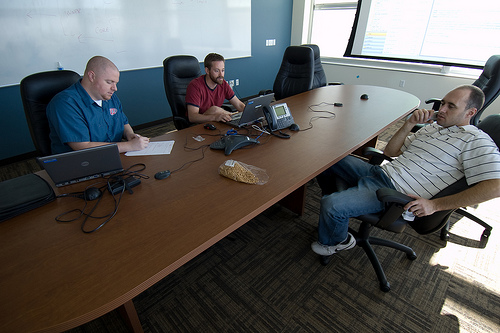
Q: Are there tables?
A: Yes, there is a table.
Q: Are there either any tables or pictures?
A: Yes, there is a table.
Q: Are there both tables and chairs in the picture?
A: Yes, there are both a table and a chair.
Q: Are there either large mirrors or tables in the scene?
A: Yes, there is a large table.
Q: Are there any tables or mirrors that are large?
A: Yes, the table is large.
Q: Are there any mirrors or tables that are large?
A: Yes, the table is large.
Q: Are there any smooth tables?
A: Yes, there is a smooth table.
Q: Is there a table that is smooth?
A: Yes, there is a table that is smooth.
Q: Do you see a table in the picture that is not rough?
A: Yes, there is a smooth table.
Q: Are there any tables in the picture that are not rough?
A: Yes, there is a smooth table.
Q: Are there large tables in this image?
A: Yes, there is a large table.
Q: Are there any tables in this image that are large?
A: Yes, there is a table that is large.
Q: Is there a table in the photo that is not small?
A: Yes, there is a large table.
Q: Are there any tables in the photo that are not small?
A: Yes, there is a large table.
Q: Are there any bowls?
A: No, there are no bowls.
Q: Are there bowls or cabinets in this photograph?
A: No, there are no bowls or cabinets.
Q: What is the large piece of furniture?
A: The piece of furniture is a table.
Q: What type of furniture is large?
A: The furniture is a table.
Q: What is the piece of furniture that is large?
A: The piece of furniture is a table.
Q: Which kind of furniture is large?
A: The furniture is a table.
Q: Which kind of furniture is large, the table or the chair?
A: The table is large.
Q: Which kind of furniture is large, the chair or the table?
A: The table is large.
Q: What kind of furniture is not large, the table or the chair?
A: The chair is not large.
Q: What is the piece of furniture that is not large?
A: The piece of furniture is a chair.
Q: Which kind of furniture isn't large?
A: The furniture is a chair.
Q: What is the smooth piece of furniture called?
A: The piece of furniture is a table.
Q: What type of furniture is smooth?
A: The furniture is a table.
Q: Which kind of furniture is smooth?
A: The furniture is a table.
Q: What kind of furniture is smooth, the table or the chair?
A: The table is smooth.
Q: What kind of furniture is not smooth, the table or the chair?
A: The chair is not smooth.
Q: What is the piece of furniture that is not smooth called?
A: The piece of furniture is a chair.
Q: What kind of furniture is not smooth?
A: The furniture is a chair.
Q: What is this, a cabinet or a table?
A: This is a table.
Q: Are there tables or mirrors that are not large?
A: No, there is a table but it is large.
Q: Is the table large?
A: Yes, the table is large.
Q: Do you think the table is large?
A: Yes, the table is large.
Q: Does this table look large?
A: Yes, the table is large.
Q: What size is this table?
A: The table is large.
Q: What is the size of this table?
A: The table is large.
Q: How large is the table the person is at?
A: The table is large.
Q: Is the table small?
A: No, the table is large.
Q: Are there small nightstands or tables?
A: No, there is a table but it is large.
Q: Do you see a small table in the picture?
A: No, there is a table but it is large.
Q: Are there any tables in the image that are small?
A: No, there is a table but it is large.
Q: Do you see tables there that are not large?
A: No, there is a table but it is large.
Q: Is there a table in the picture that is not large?
A: No, there is a table but it is large.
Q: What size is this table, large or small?
A: The table is large.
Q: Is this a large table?
A: Yes, this is a large table.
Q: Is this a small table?
A: No, this is a large table.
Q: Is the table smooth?
A: Yes, the table is smooth.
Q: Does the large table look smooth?
A: Yes, the table is smooth.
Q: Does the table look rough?
A: No, the table is smooth.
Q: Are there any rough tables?
A: No, there is a table but it is smooth.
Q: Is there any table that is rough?
A: No, there is a table but it is smooth.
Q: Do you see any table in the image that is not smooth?
A: No, there is a table but it is smooth.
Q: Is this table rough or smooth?
A: The table is smooth.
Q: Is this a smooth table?
A: Yes, this is a smooth table.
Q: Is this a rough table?
A: No, this is a smooth table.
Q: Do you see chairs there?
A: Yes, there is a chair.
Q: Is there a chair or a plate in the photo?
A: Yes, there is a chair.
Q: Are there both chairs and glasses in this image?
A: No, there is a chair but no glasses.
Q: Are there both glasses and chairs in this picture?
A: No, there is a chair but no glasses.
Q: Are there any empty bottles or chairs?
A: Yes, there is an empty chair.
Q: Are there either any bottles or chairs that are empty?
A: Yes, the chair is empty.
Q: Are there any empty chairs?
A: Yes, there is an empty chair.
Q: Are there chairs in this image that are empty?
A: Yes, there is a chair that is empty.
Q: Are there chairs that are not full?
A: Yes, there is a empty chair.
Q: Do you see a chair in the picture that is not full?
A: Yes, there is a empty chair.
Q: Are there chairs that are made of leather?
A: Yes, there is a chair that is made of leather.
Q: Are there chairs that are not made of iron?
A: Yes, there is a chair that is made of leather.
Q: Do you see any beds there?
A: No, there are no beds.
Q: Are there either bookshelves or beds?
A: No, there are no beds or bookshelves.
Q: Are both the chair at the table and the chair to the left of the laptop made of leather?
A: Yes, both the chair and the chair are made of leather.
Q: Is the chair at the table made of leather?
A: Yes, the chair is made of leather.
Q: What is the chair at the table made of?
A: The chair is made of leather.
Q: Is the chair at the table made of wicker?
A: No, the chair is made of leather.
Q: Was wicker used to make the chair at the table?
A: No, the chair is made of leather.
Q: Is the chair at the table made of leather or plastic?
A: The chair is made of leather.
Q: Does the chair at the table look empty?
A: Yes, the chair is empty.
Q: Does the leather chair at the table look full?
A: No, the chair is empty.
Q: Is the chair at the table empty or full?
A: The chair is empty.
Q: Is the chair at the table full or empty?
A: The chair is empty.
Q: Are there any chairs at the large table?
A: Yes, there is a chair at the table.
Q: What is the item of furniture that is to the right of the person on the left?
A: The piece of furniture is a chair.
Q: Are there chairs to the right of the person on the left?
A: Yes, there is a chair to the right of the person.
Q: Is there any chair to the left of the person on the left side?
A: No, the chair is to the right of the person.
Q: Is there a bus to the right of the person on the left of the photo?
A: No, there is a chair to the right of the person.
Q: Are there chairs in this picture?
A: Yes, there is a chair.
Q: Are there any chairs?
A: Yes, there is a chair.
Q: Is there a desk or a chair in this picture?
A: Yes, there is a chair.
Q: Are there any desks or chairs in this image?
A: Yes, there is a chair.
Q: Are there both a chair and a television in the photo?
A: No, there is a chair but no televisions.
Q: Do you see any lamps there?
A: No, there are no lamps.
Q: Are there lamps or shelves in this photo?
A: No, there are no lamps or shelves.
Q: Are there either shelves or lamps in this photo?
A: No, there are no lamps or shelves.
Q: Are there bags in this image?
A: Yes, there is a bag.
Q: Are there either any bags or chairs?
A: Yes, there is a bag.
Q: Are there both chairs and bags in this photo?
A: Yes, there are both a bag and a chair.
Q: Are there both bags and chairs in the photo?
A: Yes, there are both a bag and a chair.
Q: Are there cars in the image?
A: No, there are no cars.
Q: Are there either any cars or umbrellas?
A: No, there are no cars or umbrellas.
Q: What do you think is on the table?
A: The bag is on the table.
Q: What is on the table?
A: The bag is on the table.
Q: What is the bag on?
A: The bag is on the table.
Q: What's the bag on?
A: The bag is on the table.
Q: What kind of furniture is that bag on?
A: The bag is on the table.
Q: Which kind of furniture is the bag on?
A: The bag is on the table.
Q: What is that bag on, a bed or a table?
A: The bag is on a table.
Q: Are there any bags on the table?
A: Yes, there is a bag on the table.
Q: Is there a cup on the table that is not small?
A: No, there is a bag on the table.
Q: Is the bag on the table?
A: Yes, the bag is on the table.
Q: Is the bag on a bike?
A: No, the bag is on the table.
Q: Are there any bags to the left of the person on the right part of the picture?
A: Yes, there is a bag to the left of the person.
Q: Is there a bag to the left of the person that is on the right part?
A: Yes, there is a bag to the left of the person.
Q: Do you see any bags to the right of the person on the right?
A: No, the bag is to the left of the person.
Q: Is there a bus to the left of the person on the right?
A: No, there is a bag to the left of the person.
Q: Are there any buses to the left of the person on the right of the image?
A: No, there is a bag to the left of the person.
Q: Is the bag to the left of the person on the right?
A: Yes, the bag is to the left of the person.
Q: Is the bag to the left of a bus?
A: No, the bag is to the left of the person.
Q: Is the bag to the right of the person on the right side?
A: No, the bag is to the left of the person.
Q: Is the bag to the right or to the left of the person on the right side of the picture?
A: The bag is to the left of the person.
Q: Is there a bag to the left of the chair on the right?
A: Yes, there is a bag to the left of the chair.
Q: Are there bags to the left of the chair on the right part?
A: Yes, there is a bag to the left of the chair.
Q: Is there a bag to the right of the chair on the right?
A: No, the bag is to the left of the chair.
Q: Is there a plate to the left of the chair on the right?
A: No, there is a bag to the left of the chair.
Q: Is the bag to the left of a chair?
A: Yes, the bag is to the left of a chair.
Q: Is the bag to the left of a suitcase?
A: No, the bag is to the left of a chair.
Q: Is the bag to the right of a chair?
A: No, the bag is to the left of a chair.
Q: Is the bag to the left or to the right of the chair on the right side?
A: The bag is to the left of the chair.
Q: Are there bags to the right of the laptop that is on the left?
A: Yes, there is a bag to the right of the laptop.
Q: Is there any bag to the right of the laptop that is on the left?
A: Yes, there is a bag to the right of the laptop.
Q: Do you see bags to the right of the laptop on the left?
A: Yes, there is a bag to the right of the laptop.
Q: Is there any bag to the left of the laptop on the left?
A: No, the bag is to the right of the laptop.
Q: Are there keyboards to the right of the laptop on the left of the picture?
A: No, there is a bag to the right of the laptop.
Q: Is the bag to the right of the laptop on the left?
A: Yes, the bag is to the right of the laptop.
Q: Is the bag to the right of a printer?
A: No, the bag is to the right of the laptop.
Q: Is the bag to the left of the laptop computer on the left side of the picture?
A: No, the bag is to the right of the laptop computer.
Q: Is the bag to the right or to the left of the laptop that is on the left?
A: The bag is to the right of the laptop.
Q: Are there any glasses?
A: No, there are no glasses.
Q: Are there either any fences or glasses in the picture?
A: No, there are no glasses or fences.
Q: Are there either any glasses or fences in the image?
A: No, there are no glasses or fences.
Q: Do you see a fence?
A: No, there are no fences.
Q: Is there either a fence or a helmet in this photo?
A: No, there are no fences or helmets.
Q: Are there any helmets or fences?
A: No, there are no fences or helmets.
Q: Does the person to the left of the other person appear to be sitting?
A: Yes, the person is sitting.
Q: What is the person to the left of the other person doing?
A: The person is sitting.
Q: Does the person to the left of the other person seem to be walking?
A: No, the person is sitting.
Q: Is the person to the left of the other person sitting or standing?
A: The person is sitting.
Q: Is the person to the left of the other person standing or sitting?
A: The person is sitting.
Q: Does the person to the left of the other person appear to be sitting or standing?
A: The person is sitting.